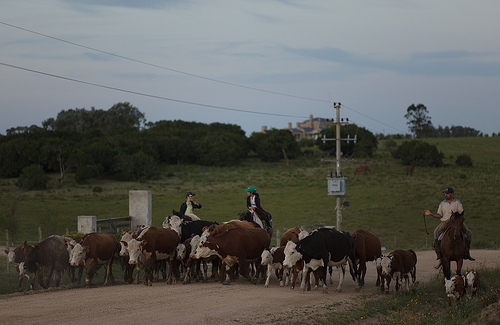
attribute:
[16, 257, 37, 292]
cow — brown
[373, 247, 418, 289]
cow — brown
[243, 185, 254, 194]
hat — green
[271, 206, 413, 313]
cow — brown, white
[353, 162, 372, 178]
horse — grazing in distance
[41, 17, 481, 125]
sky — cloudy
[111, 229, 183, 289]
cow — brown, white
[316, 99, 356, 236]
pole — utility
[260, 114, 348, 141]
home — large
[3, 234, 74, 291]
cow — white, brown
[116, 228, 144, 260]
brown cow — white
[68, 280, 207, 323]
dirt — brown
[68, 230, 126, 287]
cow — brown, white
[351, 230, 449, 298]
cow — brown, white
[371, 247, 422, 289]
cow — small